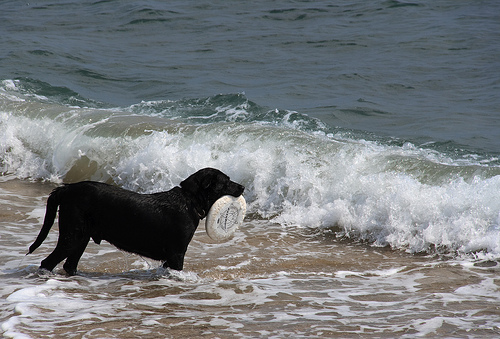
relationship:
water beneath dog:
[323, 167, 481, 284] [26, 165, 244, 275]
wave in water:
[3, 73, 499, 273] [281, 135, 405, 193]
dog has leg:
[31, 147, 223, 275] [163, 256, 184, 273]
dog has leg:
[23, 167, 249, 276] [32, 216, 77, 273]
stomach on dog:
[93, 229, 165, 262] [22, 158, 257, 282]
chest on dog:
[175, 207, 204, 258] [22, 158, 257, 282]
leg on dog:
[32, 199, 162, 307] [30, 130, 304, 305]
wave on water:
[253, 82, 476, 290] [31, 12, 484, 319]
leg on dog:
[39, 239, 66, 269] [26, 165, 244, 275]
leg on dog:
[64, 244, 88, 274] [26, 165, 244, 275]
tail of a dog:
[30, 184, 60, 262] [22, 158, 257, 282]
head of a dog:
[179, 168, 249, 208] [26, 165, 244, 275]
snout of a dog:
[230, 180, 251, 203] [31, 152, 241, 309]